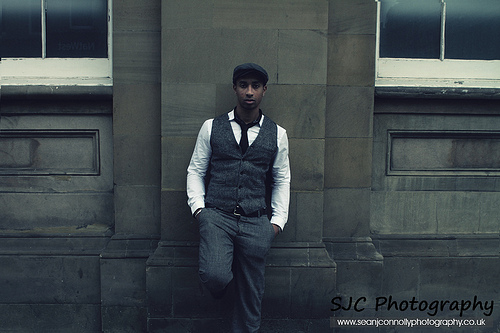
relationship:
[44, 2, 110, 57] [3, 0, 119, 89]
pane of window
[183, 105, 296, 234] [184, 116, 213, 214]
shirt has sleeve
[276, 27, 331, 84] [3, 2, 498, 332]
brick on building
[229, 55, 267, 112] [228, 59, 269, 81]
head has hat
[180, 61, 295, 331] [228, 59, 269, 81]
man has hat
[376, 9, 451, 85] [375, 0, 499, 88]
pane on window